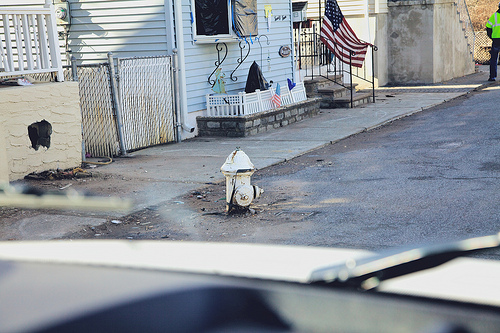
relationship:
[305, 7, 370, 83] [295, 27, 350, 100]
american flag on porch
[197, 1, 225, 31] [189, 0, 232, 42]
plastic taped around window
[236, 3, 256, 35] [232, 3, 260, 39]
plastic taped around window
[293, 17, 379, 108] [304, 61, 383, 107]
railing on stairs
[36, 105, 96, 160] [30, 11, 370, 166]
hole in wall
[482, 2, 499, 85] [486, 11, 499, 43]
man in vest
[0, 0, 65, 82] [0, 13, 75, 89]
fence around porch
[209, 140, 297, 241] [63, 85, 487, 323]
hydrant in road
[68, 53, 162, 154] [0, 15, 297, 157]
fence along a building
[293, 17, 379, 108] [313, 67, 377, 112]
railing on a staircase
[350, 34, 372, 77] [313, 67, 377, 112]
railing on a staircase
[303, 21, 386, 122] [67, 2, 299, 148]
staircase in front of a building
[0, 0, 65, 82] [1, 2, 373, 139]
fence on a building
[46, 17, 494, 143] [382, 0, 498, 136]
wall along a building